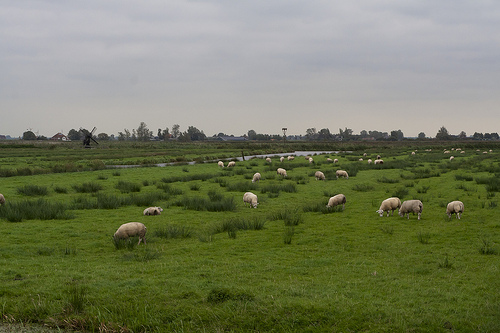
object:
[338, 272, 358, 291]
grass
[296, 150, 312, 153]
water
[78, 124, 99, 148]
windmill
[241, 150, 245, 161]
post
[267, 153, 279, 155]
water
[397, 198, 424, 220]
sheep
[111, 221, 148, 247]
sheep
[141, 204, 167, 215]
sheep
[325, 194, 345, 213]
sheep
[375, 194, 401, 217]
sheep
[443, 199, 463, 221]
sheep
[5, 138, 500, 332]
field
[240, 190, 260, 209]
sheep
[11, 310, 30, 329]
grass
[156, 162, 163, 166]
water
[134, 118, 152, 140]
trees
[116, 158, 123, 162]
crops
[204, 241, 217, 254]
grass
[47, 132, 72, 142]
farmhouse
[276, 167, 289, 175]
sheep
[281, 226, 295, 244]
gras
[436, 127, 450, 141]
tree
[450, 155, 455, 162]
sheep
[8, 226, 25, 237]
grass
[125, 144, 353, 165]
stream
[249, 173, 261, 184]
sheep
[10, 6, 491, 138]
sky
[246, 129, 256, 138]
trees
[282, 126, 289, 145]
tower